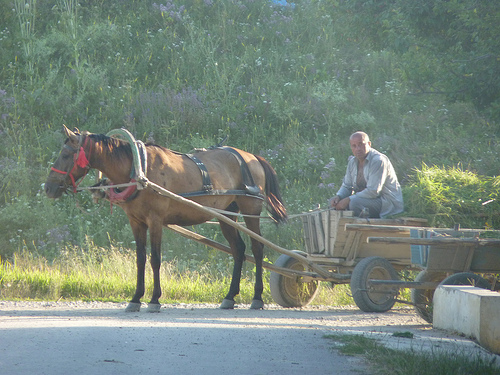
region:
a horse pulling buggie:
[32, 33, 497, 322]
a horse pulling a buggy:
[36, 56, 455, 348]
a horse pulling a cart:
[35, 30, 489, 369]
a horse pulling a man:
[41, 48, 478, 372]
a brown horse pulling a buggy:
[12, 45, 472, 374]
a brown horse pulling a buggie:
[1, 29, 498, 368]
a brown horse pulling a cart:
[9, 54, 472, 342]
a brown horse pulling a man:
[37, 51, 481, 357]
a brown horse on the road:
[27, 61, 399, 373]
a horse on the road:
[12, 63, 394, 373]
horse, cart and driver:
[40, 123, 496, 311]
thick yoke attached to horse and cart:
[95, 120, 340, 285]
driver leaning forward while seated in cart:
[325, 121, 401, 231]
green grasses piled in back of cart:
[400, 160, 495, 225]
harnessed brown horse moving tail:
[40, 120, 290, 310]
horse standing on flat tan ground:
[6, 261, 441, 367]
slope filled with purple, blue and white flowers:
[15, 0, 440, 291]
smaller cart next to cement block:
[340, 220, 499, 349]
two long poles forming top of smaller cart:
[340, 220, 495, 245]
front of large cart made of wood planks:
[295, 202, 345, 262]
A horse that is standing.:
[31, 117, 276, 324]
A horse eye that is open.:
[58, 149, 71, 161]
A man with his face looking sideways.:
[342, 126, 375, 163]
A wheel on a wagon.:
[346, 248, 406, 318]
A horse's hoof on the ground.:
[146, 295, 163, 315]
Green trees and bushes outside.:
[13, 8, 497, 126]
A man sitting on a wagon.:
[333, 132, 412, 216]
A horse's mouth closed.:
[35, 177, 69, 202]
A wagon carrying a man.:
[262, 205, 499, 317]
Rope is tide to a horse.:
[176, 188, 338, 224]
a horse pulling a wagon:
[44, 76, 489, 317]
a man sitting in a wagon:
[288, 103, 410, 285]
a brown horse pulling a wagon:
[41, 133, 426, 304]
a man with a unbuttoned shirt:
[323, 125, 388, 235]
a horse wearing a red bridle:
[28, 129, 92, 209]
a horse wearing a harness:
[92, 119, 148, 226]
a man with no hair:
[333, 123, 375, 174]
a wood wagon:
[288, 187, 446, 299]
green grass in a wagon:
[382, 159, 491, 269]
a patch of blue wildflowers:
[256, 1, 306, 18]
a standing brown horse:
[43, 124, 283, 309]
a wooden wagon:
[270, 208, 435, 310]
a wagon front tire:
[347, 252, 398, 312]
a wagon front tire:
[267, 245, 318, 308]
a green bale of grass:
[401, 165, 498, 230]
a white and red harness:
[95, 121, 149, 208]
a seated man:
[331, 128, 403, 221]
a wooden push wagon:
[344, 219, 498, 323]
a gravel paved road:
[0, 300, 425, 372]